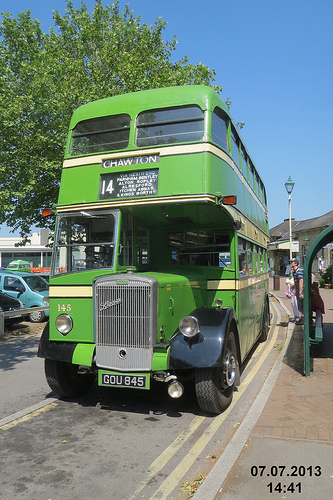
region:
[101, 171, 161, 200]
black and white bus marquee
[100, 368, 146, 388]
black and silver license plate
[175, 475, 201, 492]
a small pile of dead leaves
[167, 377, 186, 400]
a round shiny headlight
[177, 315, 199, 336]
a round shiny headlight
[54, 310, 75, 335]
a round shiny headlight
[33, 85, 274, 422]
a green vintage double decker bus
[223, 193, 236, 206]
an orange caution light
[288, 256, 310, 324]
a man wearing baseball cap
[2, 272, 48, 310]
a green van in a parking lot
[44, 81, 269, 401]
green double decker bus with yellow stripes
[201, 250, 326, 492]
people standing on curve of sidewalk on flat bricks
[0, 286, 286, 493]
gray street with oily stains and faded yellow lines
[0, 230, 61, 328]
cars parked in lot in front of white building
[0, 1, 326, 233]
deep blue sky over trees and roofs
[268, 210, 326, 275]
dark gray roof over gray building with separate overhang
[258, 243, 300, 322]
man leaning forward toward bus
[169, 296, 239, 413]
headlight over black wheel cover over tire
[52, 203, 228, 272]
recessed area next to front window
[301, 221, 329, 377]
curved green bus shelter with bench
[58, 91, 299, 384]
the bus is double decker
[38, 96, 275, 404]
the bus is blue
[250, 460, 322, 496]
photo was taken in 2013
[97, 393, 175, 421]
shadow is below the bus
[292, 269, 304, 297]
the shirt is blue and black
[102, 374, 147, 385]
the numbersplate is GOU845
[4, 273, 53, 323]
THE CAR IS BLUE IN COLOR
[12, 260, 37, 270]
the van is green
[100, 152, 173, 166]
the bus is headed to chawton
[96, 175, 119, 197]
numbre 14 is on the bus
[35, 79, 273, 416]
a green double decker bus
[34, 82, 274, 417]
a double decker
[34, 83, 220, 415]
a front of a double decker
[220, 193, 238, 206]
light of the double decker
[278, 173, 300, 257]
a light post on the side of the street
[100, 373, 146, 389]
a plate number of the bus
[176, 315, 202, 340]
a light on the front of the bus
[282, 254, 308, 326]
people standing on the sidewalk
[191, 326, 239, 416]
a front tire of the bus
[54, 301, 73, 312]
a number printed on front of the bus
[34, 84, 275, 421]
The bus is a doubledecker.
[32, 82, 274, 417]
The bus is green.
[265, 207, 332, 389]
The man is standing at the bus stop.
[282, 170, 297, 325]
The streetlamp is off.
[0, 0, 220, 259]
The tree is green.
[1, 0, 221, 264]
The tree is leafy.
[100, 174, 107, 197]
The number is white.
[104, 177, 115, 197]
The number is white.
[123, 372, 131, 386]
The number is white.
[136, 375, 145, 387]
The number is white.